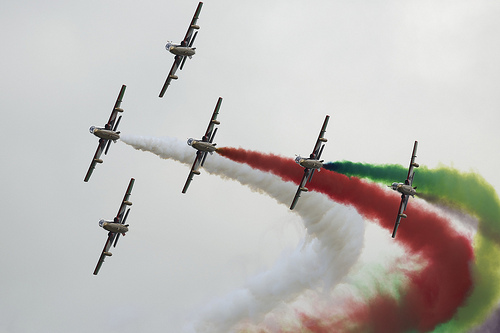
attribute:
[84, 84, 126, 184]
plane — in group, part of group, flying, in air, in flight, acrobatic, large, part of squad, flying together, flying in formation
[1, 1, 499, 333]
sky — wide open, very clear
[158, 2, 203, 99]
plane — part of squad, flying together, flying in formation, in group, part of group, flying, in air, in flight, acrobatic, large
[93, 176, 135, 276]
plane — in group, in air, in flight, flying, acrobatic, large, part of squad, flying together, flying in formation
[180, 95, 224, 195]
plane — in group, part of group, flying, in air, in flight, acrobatic, large, part of squad, flying together, flying in formation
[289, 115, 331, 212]
plane — part of squad, flying together, flying in formation, in group, part of group, flying, in air, in flight, acrobatic, large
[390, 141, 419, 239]
plane — in group, part of group, flying, in air, in flight, acrobatic, large, part of squad, flying together, flying in formation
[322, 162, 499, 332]
smoke — green, colored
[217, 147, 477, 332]
smoke — red, colored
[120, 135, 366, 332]
smoke — white, colored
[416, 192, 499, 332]
smoke — purple, colored